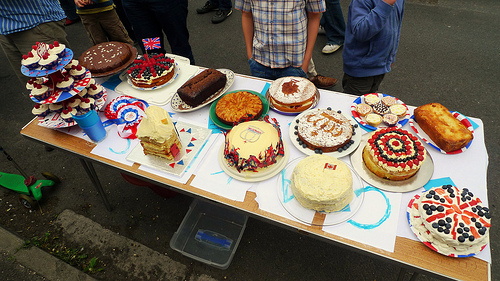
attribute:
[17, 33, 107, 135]
tower — of cupcakes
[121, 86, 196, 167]
layered cake — white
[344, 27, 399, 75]
blue shirt — blue  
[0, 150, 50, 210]
scooter —  green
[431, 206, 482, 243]
balls — black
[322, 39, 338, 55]
shoe — white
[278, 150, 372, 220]
cake — red, white, blue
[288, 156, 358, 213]
cake —  white 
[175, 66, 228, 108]
cake — Brown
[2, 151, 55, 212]
scooter — green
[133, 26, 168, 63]
flag — British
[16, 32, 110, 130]
cupcakes tower — chocolate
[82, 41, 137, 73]
cake — round, chocolate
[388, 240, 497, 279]
table — long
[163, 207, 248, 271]
box — plastic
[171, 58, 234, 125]
dessert — brown, loaf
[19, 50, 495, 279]
table —  wooden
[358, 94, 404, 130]
cookies — iced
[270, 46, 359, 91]
pockets — jean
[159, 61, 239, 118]
plate — oval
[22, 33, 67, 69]
icing — white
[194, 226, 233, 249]
label — blue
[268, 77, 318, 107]
sprinkles — white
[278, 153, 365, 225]
plate —  clear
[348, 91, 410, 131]
plates —   two,  red, white, and blue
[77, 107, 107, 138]
item — blue